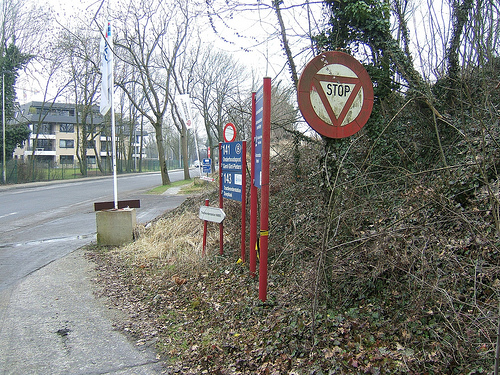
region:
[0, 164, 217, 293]
Road in a town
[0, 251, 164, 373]
Shoulder of the road at a curve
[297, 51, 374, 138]
A red STOP sign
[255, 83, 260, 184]
A blue road sign board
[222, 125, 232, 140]
A small red sign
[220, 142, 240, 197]
A blue board with some text on it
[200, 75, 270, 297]
Red poles of a few road signs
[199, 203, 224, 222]
A small white sign with letters on it and pointing in a direction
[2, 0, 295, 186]
Bare leafless trees by the roadsides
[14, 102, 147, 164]
A building on the far side of the road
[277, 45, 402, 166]
a board in top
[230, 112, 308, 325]
a board on side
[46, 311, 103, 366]
a dust in road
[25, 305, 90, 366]
a mark in road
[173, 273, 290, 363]
dust particles around the road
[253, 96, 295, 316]
a road iron pole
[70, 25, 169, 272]
a long electric pole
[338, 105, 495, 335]
a green grass around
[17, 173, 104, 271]
a clear view of road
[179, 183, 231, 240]
a small board indicating direction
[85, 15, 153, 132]
a flag on a pole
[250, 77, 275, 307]
red pole holding up a blue sign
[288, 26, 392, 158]
a round stop sign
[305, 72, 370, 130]
the word stop in a triangle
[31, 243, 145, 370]
the cement sidewalk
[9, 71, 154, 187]
a building in the distance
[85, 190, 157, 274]
a flag pole in cement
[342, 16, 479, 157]
trees on the side of the hill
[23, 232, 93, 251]
a puddle on the pavement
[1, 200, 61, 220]
the white lane marking in the road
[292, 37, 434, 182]
a board in ground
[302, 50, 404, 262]
a board in floor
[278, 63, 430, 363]
a board in grass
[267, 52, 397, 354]
a board in plants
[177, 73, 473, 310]
a group of boards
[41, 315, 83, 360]
mark in the road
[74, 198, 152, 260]
a small box in road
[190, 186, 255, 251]
a small board indicating arrow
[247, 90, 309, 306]
a red pole in road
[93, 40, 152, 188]
a white iron pole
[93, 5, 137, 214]
a flag pole is next to the road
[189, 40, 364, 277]
several signs are on the hillside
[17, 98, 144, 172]
a building is on the other side of the road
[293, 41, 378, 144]
the sign reads STOP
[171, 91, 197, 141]
a banner flag is on the pole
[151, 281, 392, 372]
several leaves are on the ground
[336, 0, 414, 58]
the leaves are green in color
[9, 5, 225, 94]
the trees do not have any leaves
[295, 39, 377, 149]
the sign is a circle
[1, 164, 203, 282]
a portion of the road